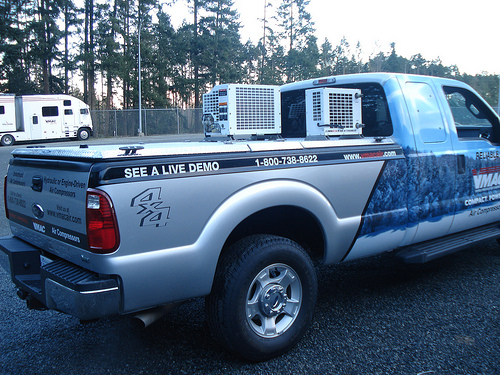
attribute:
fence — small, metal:
[90, 108, 203, 136]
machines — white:
[193, 82, 369, 142]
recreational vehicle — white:
[0, 93, 95, 146]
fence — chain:
[94, 103, 208, 139]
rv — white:
[1, 92, 96, 146]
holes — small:
[234, 85, 276, 132]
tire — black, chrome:
[209, 256, 380, 367]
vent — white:
[196, 77, 286, 144]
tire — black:
[219, 232, 323, 357]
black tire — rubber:
[207, 227, 324, 372]